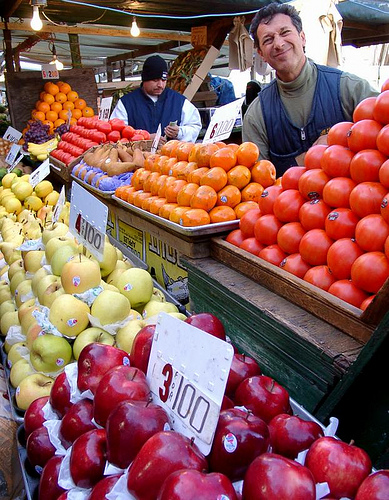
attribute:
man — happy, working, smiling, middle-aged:
[239, 0, 377, 177]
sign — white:
[143, 311, 235, 459]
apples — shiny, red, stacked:
[21, 310, 387, 498]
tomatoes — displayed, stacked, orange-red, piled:
[226, 77, 388, 311]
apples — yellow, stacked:
[0, 217, 187, 410]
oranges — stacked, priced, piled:
[17, 77, 96, 145]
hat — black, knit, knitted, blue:
[139, 52, 170, 81]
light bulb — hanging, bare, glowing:
[126, 14, 141, 39]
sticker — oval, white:
[121, 355, 131, 367]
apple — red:
[77, 343, 134, 396]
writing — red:
[156, 363, 209, 436]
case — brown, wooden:
[210, 232, 388, 342]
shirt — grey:
[241, 56, 373, 167]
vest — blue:
[256, 64, 345, 178]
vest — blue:
[117, 88, 188, 143]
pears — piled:
[0, 197, 75, 272]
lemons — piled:
[0, 169, 66, 224]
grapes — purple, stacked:
[21, 117, 69, 149]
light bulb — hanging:
[28, 6, 44, 33]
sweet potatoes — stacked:
[82, 138, 155, 178]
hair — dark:
[246, 1, 304, 50]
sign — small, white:
[38, 60, 63, 79]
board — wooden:
[5, 67, 102, 133]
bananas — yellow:
[27, 133, 61, 164]